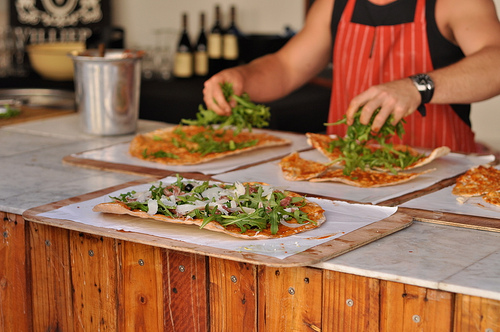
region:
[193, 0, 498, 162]
body of a woman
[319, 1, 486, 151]
an apron red on black tank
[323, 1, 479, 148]
a black tank under a red apron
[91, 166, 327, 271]
a tortilla with vegetables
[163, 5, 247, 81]
four bottles of wine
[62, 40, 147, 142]
a container of sauce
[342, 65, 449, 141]
a clock ina wrist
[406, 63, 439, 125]
clock is color silver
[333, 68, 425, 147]
left hand holding green vegetables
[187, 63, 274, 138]
right hand holding green vegetables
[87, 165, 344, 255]
a healthy and delicious pizza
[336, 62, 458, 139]
a chef wearing a watch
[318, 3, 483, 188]
a cook wearing a red apron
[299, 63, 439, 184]
a cook using green topping for pizza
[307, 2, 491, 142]
a black tank top under apron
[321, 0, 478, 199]
a red apron with white stripes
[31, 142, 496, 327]
a beautiful, rustic looking counter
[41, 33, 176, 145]
a stainless steal bucket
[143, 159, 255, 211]
an olive topped pizza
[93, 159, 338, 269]
delicious thin, crispy pizza crust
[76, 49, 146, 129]
this is a container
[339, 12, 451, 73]
this is a man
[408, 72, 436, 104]
this is a wrist watch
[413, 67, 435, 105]
the watch is black in color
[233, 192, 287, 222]
these are veges on the plate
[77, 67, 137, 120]
the container is metallic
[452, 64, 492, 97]
the hand is white in color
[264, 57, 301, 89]
this is the hand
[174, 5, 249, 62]
these are bottles of wine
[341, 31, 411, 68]
this is an overall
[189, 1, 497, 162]
a woman in front of a counter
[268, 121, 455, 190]
a tortilla is broken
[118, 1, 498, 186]
a woman putting green vegetables on tortillas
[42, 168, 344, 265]
a tortilla is over a white paper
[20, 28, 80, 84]
yellow bowl on a counter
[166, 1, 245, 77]
four bottles in a kitchen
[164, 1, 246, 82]
bottles has yellow labels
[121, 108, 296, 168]
green vegetables on tortilla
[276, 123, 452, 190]
cutted vegetables on tortilla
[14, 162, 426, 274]
tortilla has wood board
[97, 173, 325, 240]
a thin crust of a homemade pizza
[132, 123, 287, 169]
a thin crust of a homemade pizza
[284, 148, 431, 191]
a thin crust of a homemade pizza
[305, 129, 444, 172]
a thin crust of a homemade pizza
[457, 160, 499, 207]
a thin crust of a homemade pizza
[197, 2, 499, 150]
a chef making pizza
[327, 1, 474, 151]
a white and red apron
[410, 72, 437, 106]
a black and grey watch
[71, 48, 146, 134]
a tall metal bucket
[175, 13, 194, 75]
a bottle of wine